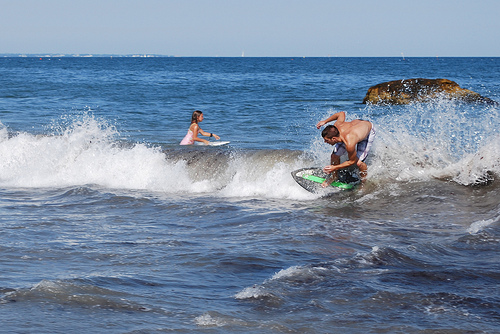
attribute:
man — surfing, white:
[311, 106, 391, 191]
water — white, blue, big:
[6, 62, 280, 304]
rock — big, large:
[363, 69, 476, 122]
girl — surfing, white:
[177, 101, 240, 152]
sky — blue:
[40, 4, 447, 59]